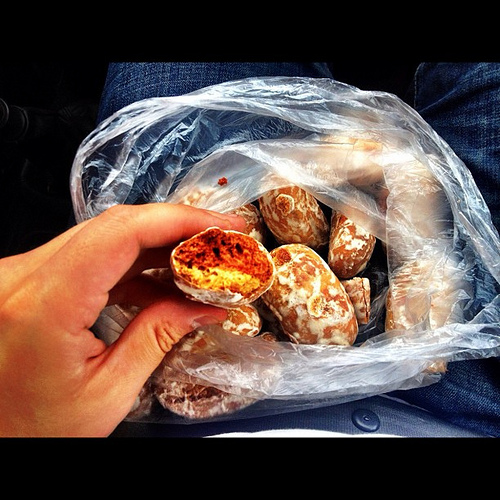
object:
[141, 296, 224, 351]
thumb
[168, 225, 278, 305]
bite-size snack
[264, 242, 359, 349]
bite-size snack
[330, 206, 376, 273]
bite-size snack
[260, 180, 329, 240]
bite-size snack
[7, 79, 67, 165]
gear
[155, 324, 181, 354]
knuckle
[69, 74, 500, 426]
bag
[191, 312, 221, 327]
thumb nail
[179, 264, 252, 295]
ingredients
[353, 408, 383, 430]
button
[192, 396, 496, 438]
seat belt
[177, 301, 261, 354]
food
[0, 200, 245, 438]
hand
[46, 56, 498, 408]
blue jeans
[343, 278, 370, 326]
pastry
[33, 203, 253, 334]
index finger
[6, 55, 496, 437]
person